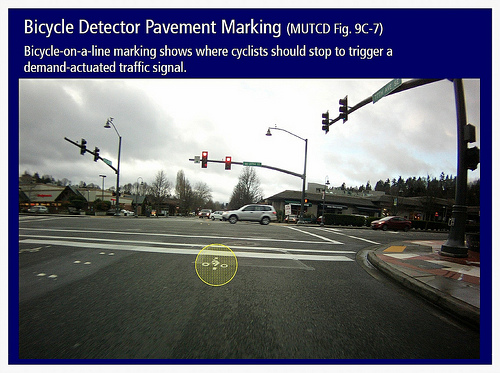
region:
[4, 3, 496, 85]
this is an ad banner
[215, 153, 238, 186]
this is a street light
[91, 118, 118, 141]
this is a street light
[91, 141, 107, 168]
this is a street light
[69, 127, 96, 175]
this is a street light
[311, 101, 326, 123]
this is a street light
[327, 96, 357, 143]
this is a street light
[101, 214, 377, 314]
a white line on the road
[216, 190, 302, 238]
the SUV is silver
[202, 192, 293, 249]
the SUV is silver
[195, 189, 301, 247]
the SUV is silver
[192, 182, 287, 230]
the SUV is silver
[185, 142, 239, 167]
the lights are red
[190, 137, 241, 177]
the lights are red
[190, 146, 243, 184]
the lights are red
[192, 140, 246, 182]
the lights are red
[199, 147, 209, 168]
TRAFFIC LIGHT LIT UP TO RED FACING CAMERA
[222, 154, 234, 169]
TRAFFIC LIGHT LIT UP TO RED FACING THE CAMERA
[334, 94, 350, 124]
TRAFFIC LIGHT ON RIGHT SIDE OF ROAD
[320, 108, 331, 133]
TRAFFIC LIGHT ON RIGHT SIDE OF ROAD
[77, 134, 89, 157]
TRAFFIC LIGHT ON LEFT SIDE OF ROAD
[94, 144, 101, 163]
TRAFFIC LIGHT ON LEFT SIDE OF ROAD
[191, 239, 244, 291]
YELLOW CIRCLE INDICATING WHERE A CYCLIST SHOULD STOP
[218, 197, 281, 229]
SILVER SUV TYPE VEHICLE CROSSING THE ROAD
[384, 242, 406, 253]
ORANGE SPOT ON THE SIDEWALK WHERE PEDESTRIANS SHOULD STAND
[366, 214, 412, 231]
RED VEHICLE WAITING AT THE TRAFFIC LIGHT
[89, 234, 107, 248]
marking on the road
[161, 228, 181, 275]
marking on the road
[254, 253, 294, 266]
marking on the road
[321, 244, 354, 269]
marking on the road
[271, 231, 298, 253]
marking on the road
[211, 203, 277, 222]
this is a car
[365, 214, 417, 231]
this is a car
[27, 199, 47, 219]
this is a car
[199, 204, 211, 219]
this is a car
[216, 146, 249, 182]
this is a street light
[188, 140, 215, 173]
this is a street light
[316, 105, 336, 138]
this is a street light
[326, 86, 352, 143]
this is a street light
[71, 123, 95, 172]
this is a street light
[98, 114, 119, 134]
this is a street light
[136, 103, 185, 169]
this is a cloud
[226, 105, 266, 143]
this is a cloud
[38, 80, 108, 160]
this is a cloud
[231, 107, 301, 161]
this is a cloud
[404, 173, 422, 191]
green leaves on the tree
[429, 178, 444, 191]
green leaves on the tree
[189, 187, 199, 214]
green leaves on the tree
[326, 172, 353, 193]
green leaves on the tree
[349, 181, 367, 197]
green leaves on the tree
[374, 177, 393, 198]
green leaves on the tree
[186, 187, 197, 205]
green leaves on the tree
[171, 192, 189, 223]
green leaves on the tree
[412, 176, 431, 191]
green leaves on the tree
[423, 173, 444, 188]
green leaves on the tree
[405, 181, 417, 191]
green leaves on the tree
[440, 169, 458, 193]
green leaves on the tree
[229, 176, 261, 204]
green leaves on the tree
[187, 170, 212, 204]
green leaves on the tree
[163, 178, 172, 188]
green leaves on the tree